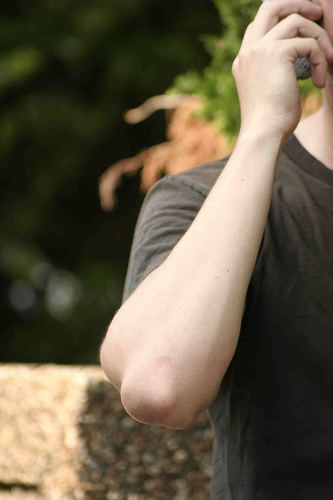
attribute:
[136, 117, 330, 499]
shirt — tee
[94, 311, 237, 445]
elbow — someones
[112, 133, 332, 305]
shirt — brown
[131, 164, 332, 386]
shirt — grey